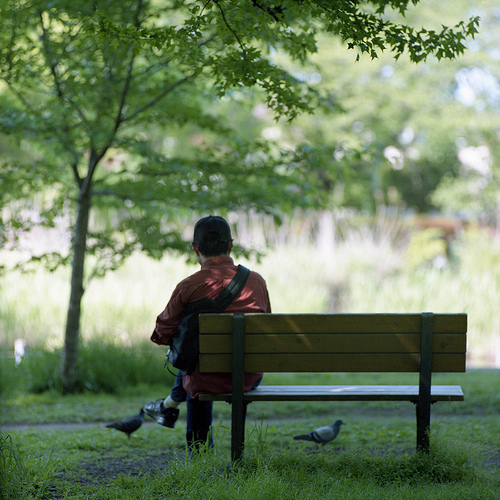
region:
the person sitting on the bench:
[138, 212, 268, 453]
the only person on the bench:
[144, 212, 266, 455]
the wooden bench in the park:
[193, 307, 466, 451]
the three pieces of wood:
[200, 312, 467, 375]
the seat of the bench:
[196, 382, 463, 399]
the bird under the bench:
[291, 417, 345, 446]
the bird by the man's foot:
[109, 407, 144, 439]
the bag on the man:
[164, 264, 251, 365]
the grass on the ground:
[186, 455, 339, 499]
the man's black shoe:
[141, 401, 181, 427]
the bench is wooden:
[133, 231, 438, 453]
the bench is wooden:
[202, 336, 374, 496]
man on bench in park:
[1, 0, 498, 499]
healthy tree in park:
[0, 0, 481, 383]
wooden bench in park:
[193, 310, 470, 462]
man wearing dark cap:
[140, 214, 273, 459]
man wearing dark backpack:
[137, 213, 273, 461]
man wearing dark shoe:
[142, 214, 273, 460]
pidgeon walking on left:
[104, 406, 146, 441]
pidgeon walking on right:
[292, 418, 347, 450]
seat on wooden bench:
[196, 383, 463, 401]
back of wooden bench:
[196, 311, 466, 373]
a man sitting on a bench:
[140, 216, 277, 464]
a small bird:
[290, 419, 350, 452]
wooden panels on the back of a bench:
[198, 313, 465, 372]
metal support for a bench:
[231, 316, 246, 459]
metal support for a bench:
[418, 313, 432, 453]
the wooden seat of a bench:
[259, 385, 464, 401]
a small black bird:
[106, 408, 143, 440]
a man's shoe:
[142, 398, 179, 430]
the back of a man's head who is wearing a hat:
[188, 214, 236, 265]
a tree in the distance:
[1, 3, 156, 396]